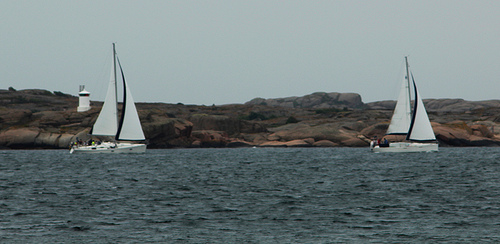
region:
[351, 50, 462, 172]
A white sailboat on the right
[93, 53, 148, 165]
A white sailboat on the left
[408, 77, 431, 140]
Blue and white sail on right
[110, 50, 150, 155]
A blue and white sail on left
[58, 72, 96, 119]
A white lighthouse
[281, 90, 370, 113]
A large rock mountain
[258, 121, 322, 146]
Rocks along the embankment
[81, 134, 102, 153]
Someone in yellow on boat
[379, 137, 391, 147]
Someone in blue on boat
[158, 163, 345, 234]
Rippled looking water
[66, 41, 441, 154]
Couple of ships in the water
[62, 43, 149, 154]
Ship with a sail flag on top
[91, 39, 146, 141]
Sail flag used to control current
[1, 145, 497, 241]
Large body of water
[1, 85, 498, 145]
Body of land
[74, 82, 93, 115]
Lighthouse away from the water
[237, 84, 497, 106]
Group of rocks on the land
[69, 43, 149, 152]
Ship sailing in the water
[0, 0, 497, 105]
Gray sky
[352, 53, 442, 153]
Ship in front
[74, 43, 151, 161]
white sailboat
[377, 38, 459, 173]
white sailboat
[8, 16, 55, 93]
white clouds in blue sky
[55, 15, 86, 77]
white clouds in blue sky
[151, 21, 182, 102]
white clouds in blue sky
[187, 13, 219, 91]
white clouds in blue sky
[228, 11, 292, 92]
white clouds in blue sky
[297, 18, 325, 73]
white clouds in blue sky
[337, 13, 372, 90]
white clouds in blue sky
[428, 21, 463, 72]
white clouds in blue sky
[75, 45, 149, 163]
white sail boat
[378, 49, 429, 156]
white sail boat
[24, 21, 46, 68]
white clouds in blue sky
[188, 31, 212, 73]
white clouds in blue sky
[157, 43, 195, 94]
white clouds in blue sky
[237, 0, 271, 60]
white clouds in blue sky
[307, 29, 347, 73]
white clouds in blue sky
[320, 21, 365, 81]
white clouds in blue sky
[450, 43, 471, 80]
white clouds in blue sky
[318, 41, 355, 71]
white clouds in blue sky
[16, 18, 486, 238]
these are sailboats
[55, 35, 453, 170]
the boats are sailing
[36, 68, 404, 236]
this looks like a river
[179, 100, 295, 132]
this is the waterfront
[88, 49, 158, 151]
the sails are white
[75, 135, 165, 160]
the boat is white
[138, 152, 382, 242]
the water is blue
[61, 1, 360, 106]
the sky is cloudy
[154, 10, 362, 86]
the clouds are gray and white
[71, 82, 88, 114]
this is a building